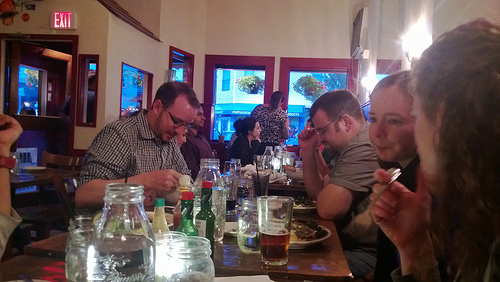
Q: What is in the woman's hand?
A: A fork.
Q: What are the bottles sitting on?
A: A table.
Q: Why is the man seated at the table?
A: To eat.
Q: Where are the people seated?
A: Dining table.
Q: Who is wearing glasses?
A: The guys.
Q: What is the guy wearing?
A: Glasses.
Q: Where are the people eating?
A: In a restaurant.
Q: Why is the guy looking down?
A: Ready to eat.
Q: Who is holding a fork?
A: Lady with red hair.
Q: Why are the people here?
A: Hungry.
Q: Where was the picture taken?
A: At a restaurant.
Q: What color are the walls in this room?
A: White.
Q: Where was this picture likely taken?
A: A restaurant.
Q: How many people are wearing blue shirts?
A: Zero.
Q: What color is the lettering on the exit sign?
A: Red.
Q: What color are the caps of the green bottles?
A: Red.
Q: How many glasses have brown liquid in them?
A: One.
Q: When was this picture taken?
A: Daytime.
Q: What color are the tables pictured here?
A: Brown.